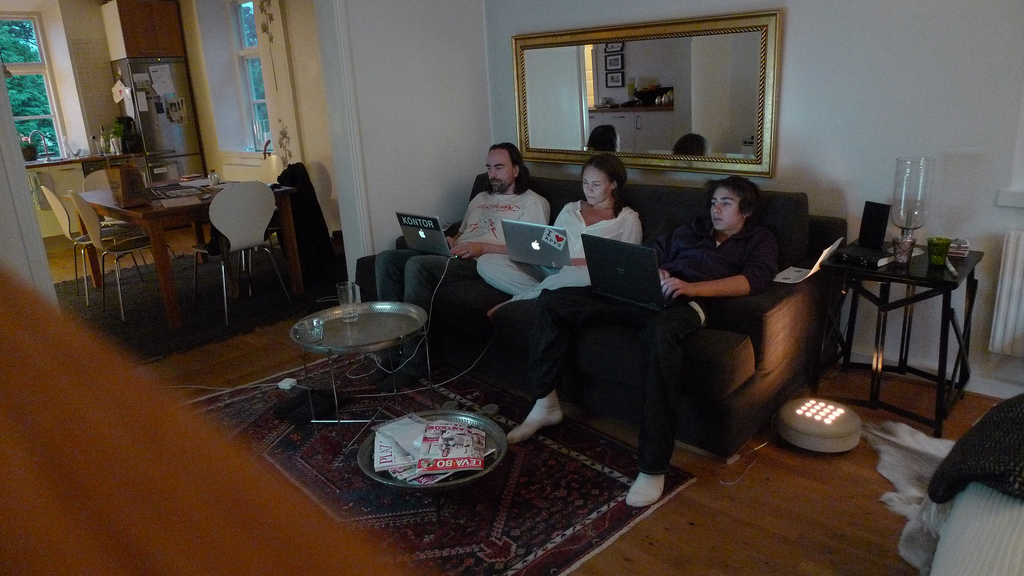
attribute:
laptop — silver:
[499, 214, 575, 273]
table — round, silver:
[285, 296, 437, 428]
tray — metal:
[350, 404, 513, 493]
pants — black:
[521, 282, 710, 475]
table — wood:
[73, 178, 316, 336]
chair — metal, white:
[58, 184, 160, 329]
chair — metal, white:
[37, 182, 139, 312]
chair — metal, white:
[188, 176, 299, 330]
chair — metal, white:
[76, 163, 176, 287]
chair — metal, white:
[240, 154, 321, 304]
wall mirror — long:
[519, 29, 764, 164]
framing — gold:
[508, 5, 789, 183]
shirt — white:
[454, 184, 552, 260]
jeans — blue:
[370, 238, 483, 368]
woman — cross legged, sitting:
[435, 122, 680, 390]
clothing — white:
[532, 184, 675, 336]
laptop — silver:
[476, 180, 598, 306]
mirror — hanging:
[476, 11, 915, 191]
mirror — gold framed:
[502, 7, 853, 178]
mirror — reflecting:
[502, 18, 855, 250]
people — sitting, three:
[375, 145, 810, 474]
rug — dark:
[182, 331, 625, 571]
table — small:
[787, 219, 973, 390]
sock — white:
[586, 443, 725, 547]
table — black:
[798, 201, 999, 463]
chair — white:
[124, 162, 375, 279]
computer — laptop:
[537, 229, 775, 353]